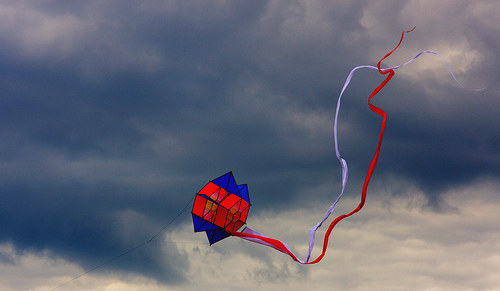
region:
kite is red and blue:
[191, 27, 437, 264]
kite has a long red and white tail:
[240, 23, 440, 269]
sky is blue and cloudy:
[3, 1, 498, 288]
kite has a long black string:
[43, 194, 196, 289]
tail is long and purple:
[240, 49, 438, 263]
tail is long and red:
[233, 25, 416, 263]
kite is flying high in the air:
[191, 26, 437, 266]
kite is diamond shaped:
[189, 172, 254, 245]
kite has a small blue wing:
[195, 191, 227, 208]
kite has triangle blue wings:
[211, 169, 251, 204]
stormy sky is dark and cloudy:
[0, 1, 498, 288]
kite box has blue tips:
[192, 171, 251, 245]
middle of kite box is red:
[192, 179, 248, 233]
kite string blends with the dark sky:
[49, 192, 196, 289]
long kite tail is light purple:
[236, 48, 488, 264]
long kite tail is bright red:
[235, 28, 417, 265]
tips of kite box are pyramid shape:
[189, 169, 250, 245]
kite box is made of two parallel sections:
[192, 169, 252, 246]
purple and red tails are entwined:
[232, 24, 438, 266]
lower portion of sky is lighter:
[0, 176, 499, 289]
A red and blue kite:
[187, 173, 251, 240]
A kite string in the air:
[0, 193, 203, 285]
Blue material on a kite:
[190, 213, 232, 250]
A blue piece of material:
[208, 167, 254, 201]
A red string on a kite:
[318, 24, 413, 265]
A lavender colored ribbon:
[301, 35, 373, 262]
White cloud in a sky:
[21, 13, 153, 78]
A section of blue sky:
[24, 225, 124, 265]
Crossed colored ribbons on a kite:
[280, 27, 484, 274]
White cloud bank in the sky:
[122, 165, 499, 285]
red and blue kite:
[192, 164, 254, 261]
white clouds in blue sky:
[67, 44, 97, 78]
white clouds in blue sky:
[198, 29, 235, 62]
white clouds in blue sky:
[397, 247, 418, 263]